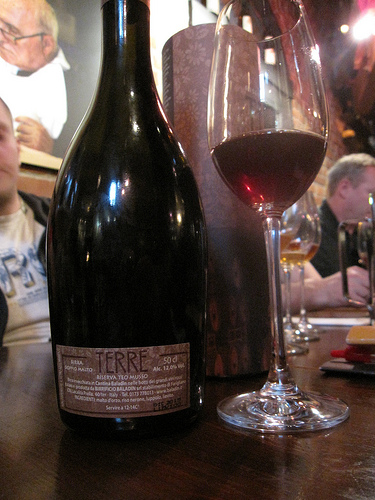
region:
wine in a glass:
[206, 0, 351, 434]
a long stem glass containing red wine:
[207, 0, 351, 433]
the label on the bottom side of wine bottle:
[54, 343, 191, 416]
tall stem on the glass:
[261, 216, 288, 384]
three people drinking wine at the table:
[0, 96, 373, 498]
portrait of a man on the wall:
[0, 1, 102, 170]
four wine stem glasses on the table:
[206, 0, 349, 433]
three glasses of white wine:
[281, 190, 321, 357]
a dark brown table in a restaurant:
[0, 308, 374, 498]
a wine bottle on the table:
[45, 1, 208, 441]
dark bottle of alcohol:
[46, 107, 209, 444]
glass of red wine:
[211, 124, 342, 440]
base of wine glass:
[219, 385, 350, 437]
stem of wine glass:
[262, 254, 290, 369]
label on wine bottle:
[59, 336, 198, 418]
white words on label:
[74, 369, 175, 414]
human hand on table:
[312, 260, 365, 313]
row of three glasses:
[280, 218, 324, 341]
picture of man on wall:
[6, 5, 73, 81]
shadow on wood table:
[81, 436, 184, 484]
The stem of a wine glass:
[237, 198, 338, 435]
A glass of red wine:
[196, 36, 334, 232]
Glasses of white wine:
[270, 207, 336, 271]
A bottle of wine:
[53, 7, 222, 428]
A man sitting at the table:
[322, 136, 369, 304]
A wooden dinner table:
[4, 400, 289, 496]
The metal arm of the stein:
[335, 214, 370, 328]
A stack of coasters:
[315, 311, 371, 373]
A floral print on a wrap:
[171, 31, 218, 113]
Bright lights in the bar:
[309, 7, 371, 40]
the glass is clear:
[176, 1, 371, 251]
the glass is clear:
[186, 36, 310, 224]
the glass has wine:
[194, 22, 333, 251]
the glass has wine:
[207, 19, 294, 205]